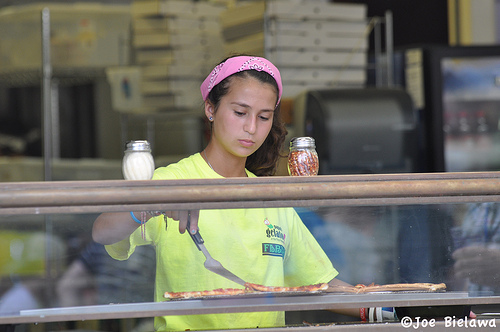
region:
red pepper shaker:
[280, 135, 332, 183]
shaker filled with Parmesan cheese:
[122, 137, 157, 179]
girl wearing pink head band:
[185, 49, 287, 164]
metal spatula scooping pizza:
[167, 216, 282, 300]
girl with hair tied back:
[194, 54, 300, 175]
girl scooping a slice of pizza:
[171, 55, 361, 315]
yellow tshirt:
[155, 143, 299, 328]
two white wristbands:
[350, 298, 390, 324]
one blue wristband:
[116, 210, 153, 232]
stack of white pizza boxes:
[227, 0, 374, 97]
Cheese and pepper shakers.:
[101, 124, 361, 201]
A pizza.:
[143, 267, 449, 297]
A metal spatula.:
[171, 213, 275, 295]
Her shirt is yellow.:
[78, 138, 342, 329]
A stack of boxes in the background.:
[124, 0, 374, 98]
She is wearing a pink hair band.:
[178, 31, 287, 161]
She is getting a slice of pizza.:
[78, 144, 355, 302]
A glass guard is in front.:
[2, 186, 497, 311]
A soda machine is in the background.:
[393, 34, 495, 296]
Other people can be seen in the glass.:
[2, 183, 496, 304]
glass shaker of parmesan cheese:
[119, 134, 159, 184]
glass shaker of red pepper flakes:
[284, 129, 325, 181]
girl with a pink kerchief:
[188, 51, 280, 172]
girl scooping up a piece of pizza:
[91, 41, 347, 309]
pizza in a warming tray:
[165, 261, 445, 301]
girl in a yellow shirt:
[100, 31, 325, 322]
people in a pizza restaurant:
[11, 219, 150, 303]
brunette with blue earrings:
[187, 49, 282, 164]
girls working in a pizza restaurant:
[80, 31, 375, 320]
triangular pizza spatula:
[176, 219, 268, 297]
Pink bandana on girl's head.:
[206, 47, 336, 122]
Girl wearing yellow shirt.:
[189, 217, 272, 296]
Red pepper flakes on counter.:
[283, 136, 330, 193]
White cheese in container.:
[123, 140, 182, 205]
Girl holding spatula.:
[173, 208, 250, 320]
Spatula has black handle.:
[187, 212, 228, 277]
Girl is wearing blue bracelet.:
[125, 207, 139, 225]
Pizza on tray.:
[163, 271, 380, 326]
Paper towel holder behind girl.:
[283, 87, 443, 264]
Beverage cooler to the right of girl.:
[442, 60, 496, 153]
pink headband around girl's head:
[142, 41, 299, 153]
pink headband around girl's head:
[198, 55, 252, 96]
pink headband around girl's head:
[186, 62, 335, 159]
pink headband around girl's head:
[206, 62, 277, 180]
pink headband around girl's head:
[135, 40, 348, 229]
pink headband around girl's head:
[162, 49, 292, 315]